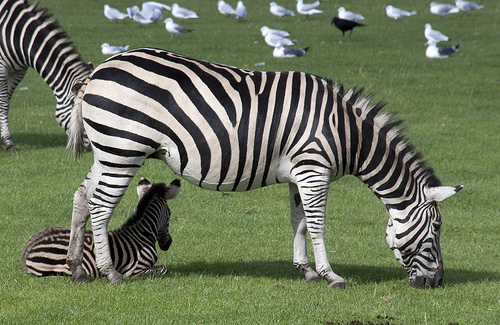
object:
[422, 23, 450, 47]
bird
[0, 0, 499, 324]
field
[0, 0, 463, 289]
three zebras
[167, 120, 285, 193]
belly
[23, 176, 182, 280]
zebra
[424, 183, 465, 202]
ear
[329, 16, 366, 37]
bird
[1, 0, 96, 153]
zebra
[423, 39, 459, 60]
bird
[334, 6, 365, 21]
bird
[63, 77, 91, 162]
tail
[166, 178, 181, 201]
ear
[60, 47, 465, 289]
stripes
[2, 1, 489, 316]
zebras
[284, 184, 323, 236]
spot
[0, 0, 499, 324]
grass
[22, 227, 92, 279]
dirt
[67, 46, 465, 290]
animal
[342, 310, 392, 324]
droppings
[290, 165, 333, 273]
leg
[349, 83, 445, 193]
hair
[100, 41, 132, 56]
birds